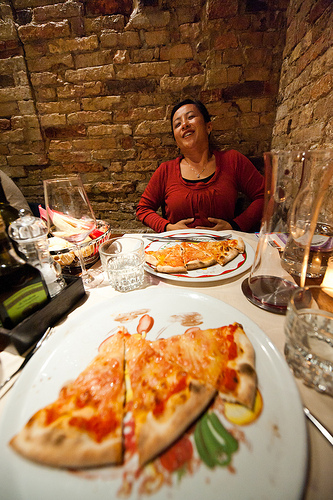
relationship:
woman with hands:
[132, 95, 279, 235] [158, 202, 247, 232]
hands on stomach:
[158, 202, 247, 232] [185, 215, 213, 226]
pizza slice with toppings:
[161, 241, 204, 274] [213, 243, 230, 250]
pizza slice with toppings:
[200, 236, 239, 263] [209, 239, 225, 255]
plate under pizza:
[139, 226, 254, 283] [144, 237, 244, 273]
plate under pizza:
[0, 284, 307, 496] [8, 319, 255, 468]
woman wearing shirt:
[132, 95, 279, 235] [132, 148, 263, 230]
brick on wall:
[2, 1, 284, 187] [15, 13, 282, 238]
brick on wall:
[134, 119, 173, 132] [2, 1, 288, 234]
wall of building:
[2, 1, 288, 234] [1, 0, 331, 234]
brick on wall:
[131, 48, 159, 61] [114, 14, 234, 101]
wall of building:
[114, 14, 234, 101] [1, 0, 331, 234]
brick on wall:
[93, 147, 138, 160] [49, 24, 169, 117]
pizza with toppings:
[151, 237, 247, 271] [72, 374, 199, 416]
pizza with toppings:
[34, 318, 261, 472] [72, 374, 199, 416]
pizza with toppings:
[151, 237, 247, 271] [159, 249, 220, 262]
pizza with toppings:
[151, 237, 247, 271] [81, 368, 165, 441]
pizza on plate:
[34, 318, 261, 472] [0, 284, 307, 496]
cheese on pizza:
[37, 325, 223, 421] [8, 324, 259, 492]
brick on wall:
[78, 96, 124, 108] [2, 1, 288, 234]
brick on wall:
[94, 179, 132, 193] [64, 122, 161, 180]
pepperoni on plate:
[162, 433, 192, 468] [0, 284, 307, 496]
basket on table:
[47, 220, 112, 273] [1, 231, 332, 498]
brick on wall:
[296, 30, 325, 71] [271, 0, 331, 237]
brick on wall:
[269, 120, 291, 133] [271, 0, 331, 237]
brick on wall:
[47, 33, 100, 54] [2, 1, 288, 234]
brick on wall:
[128, 60, 171, 76] [2, 1, 288, 234]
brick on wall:
[214, 29, 241, 49] [271, 0, 331, 237]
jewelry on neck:
[173, 161, 215, 180] [178, 148, 216, 179]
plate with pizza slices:
[131, 223, 261, 291] [148, 232, 239, 274]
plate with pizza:
[131, 223, 261, 291] [180, 237, 216, 269]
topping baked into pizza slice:
[64, 409, 119, 441] [7, 328, 124, 469]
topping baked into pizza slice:
[70, 394, 88, 409] [7, 328, 124, 469]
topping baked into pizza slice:
[69, 331, 125, 400] [7, 328, 124, 469]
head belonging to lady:
[169, 97, 214, 150] [130, 97, 274, 237]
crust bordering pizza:
[135, 382, 222, 458] [16, 328, 274, 464]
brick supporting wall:
[47, 33, 100, 54] [1, 2, 330, 231]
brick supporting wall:
[221, 76, 269, 106] [1, 2, 330, 231]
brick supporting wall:
[288, 32, 327, 75] [1, 2, 330, 231]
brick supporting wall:
[90, 142, 137, 164] [1, 2, 330, 231]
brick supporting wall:
[128, 60, 171, 76] [1, 2, 330, 231]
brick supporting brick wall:
[290, 121, 322, 146] [275, 10, 332, 143]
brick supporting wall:
[66, 109, 113, 124] [2, 1, 288, 234]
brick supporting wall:
[60, 63, 118, 80] [2, 1, 288, 234]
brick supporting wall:
[99, 30, 142, 48] [2, 1, 288, 234]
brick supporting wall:
[45, 32, 98, 53] [2, 1, 288, 234]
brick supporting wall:
[0, 85, 33, 101] [2, 1, 288, 234]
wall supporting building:
[2, 1, 288, 234] [3, 2, 319, 284]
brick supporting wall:
[35, 100, 61, 113] [32, 0, 155, 176]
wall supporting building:
[32, 0, 155, 176] [3, 2, 319, 284]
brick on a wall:
[221, 76, 269, 106] [140, 27, 255, 94]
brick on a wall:
[224, 69, 271, 78] [140, 27, 255, 94]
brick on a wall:
[160, 73, 208, 87] [140, 27, 255, 94]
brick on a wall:
[206, 67, 264, 77] [140, 27, 255, 94]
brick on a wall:
[242, 96, 269, 110] [140, 27, 255, 94]